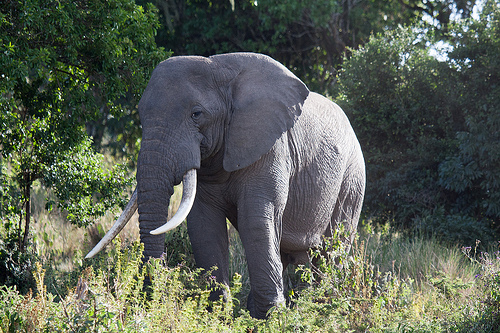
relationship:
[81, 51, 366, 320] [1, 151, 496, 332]
elephant standing in clearing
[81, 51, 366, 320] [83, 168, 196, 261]
elephant has tusks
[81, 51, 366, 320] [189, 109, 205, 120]
elephant has eye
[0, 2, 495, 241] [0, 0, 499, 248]
trees have leaves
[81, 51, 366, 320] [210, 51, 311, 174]
elephant has ear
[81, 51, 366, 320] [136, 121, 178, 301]
elephant has trunk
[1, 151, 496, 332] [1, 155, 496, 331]
clearing has grass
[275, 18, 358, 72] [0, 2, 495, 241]
dead branches are in trees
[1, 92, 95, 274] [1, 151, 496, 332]
tree in clearing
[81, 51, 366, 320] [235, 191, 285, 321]
elephant has leg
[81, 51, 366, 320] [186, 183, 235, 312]
elephant has leg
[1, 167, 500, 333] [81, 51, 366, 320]
grass are near elephant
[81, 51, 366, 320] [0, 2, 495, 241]
elephant near trees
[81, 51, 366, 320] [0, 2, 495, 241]
elephant standing among trees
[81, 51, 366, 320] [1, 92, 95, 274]
elephant near tree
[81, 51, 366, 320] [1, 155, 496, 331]
elephant walking through grass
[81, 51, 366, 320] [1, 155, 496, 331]
elephant standing in grass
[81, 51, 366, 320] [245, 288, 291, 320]
elephant has foot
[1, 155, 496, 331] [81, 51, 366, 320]
grass under elephant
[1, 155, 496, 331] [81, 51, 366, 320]
grass beneath elephant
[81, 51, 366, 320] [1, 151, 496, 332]
elephant in clearing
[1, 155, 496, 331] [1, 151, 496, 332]
grass on clearing